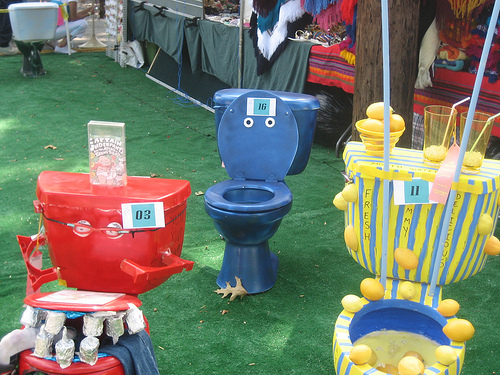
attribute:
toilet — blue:
[194, 94, 340, 309]